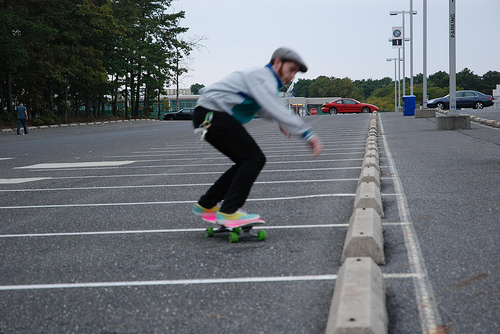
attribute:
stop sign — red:
[308, 105, 318, 115]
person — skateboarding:
[185, 45, 320, 242]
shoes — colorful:
[182, 181, 274, 243]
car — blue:
[418, 86, 499, 111]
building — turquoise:
[116, 90, 199, 121]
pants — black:
[186, 105, 278, 232]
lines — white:
[62, 119, 230, 281]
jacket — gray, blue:
[196, 65, 316, 142]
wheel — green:
[255, 227, 268, 241]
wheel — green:
[225, 229, 239, 243]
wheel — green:
[203, 224, 213, 238]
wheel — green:
[233, 227, 241, 234]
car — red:
[311, 87, 376, 120]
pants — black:
[186, 102, 272, 218]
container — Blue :
[403, 92, 417, 114]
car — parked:
[320, 97, 377, 114]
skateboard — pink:
[200, 204, 269, 242]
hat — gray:
[269, 25, 310, 71]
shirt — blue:
[16, 106, 26, 116]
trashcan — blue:
[400, 91, 415, 118]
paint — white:
[44, 169, 198, 293]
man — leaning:
[189, 46, 323, 228]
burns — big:
[277, 60, 286, 78]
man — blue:
[13, 101, 30, 133]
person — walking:
[12, 101, 29, 133]